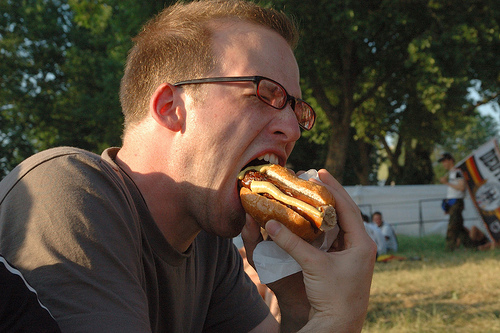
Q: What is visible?
A: Spectacles.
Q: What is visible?
A: A man.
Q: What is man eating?
A: Hotdog.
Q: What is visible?
A: A tree.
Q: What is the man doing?
A: Eating.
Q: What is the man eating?
A: A hot dog.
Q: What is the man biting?
A: A sandwich.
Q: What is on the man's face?
A: Glasses.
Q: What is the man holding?
A: A sandwich.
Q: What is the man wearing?
A: A brown shirt.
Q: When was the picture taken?
A: Daytime.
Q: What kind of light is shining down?
A: Sunlight.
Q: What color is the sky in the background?
A: Blue.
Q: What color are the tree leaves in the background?
A: Green.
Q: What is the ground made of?
A: Grass.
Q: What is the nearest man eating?
A: A hot dog.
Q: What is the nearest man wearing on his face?
A: Glasses.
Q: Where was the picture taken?
A: Outside in the park.